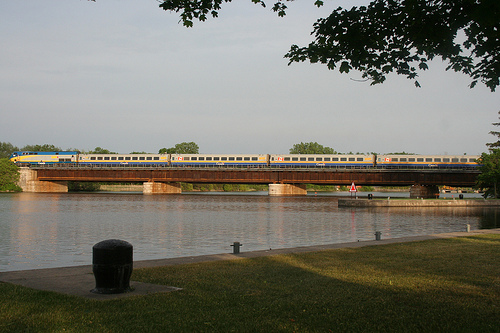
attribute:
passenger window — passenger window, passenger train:
[182, 155, 189, 162]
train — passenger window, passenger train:
[49, 142, 386, 184]